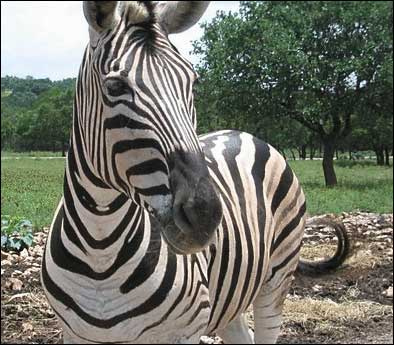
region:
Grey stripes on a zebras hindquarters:
[242, 141, 309, 240]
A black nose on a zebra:
[151, 145, 229, 249]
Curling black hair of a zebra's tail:
[292, 211, 356, 278]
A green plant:
[4, 210, 30, 252]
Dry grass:
[289, 290, 382, 324]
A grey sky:
[10, 7, 72, 58]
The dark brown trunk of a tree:
[287, 104, 346, 181]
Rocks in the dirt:
[6, 222, 49, 287]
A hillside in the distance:
[8, 70, 65, 124]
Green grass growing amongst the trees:
[297, 158, 382, 209]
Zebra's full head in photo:
[69, 2, 234, 255]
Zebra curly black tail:
[296, 203, 354, 287]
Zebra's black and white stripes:
[212, 236, 264, 297]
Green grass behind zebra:
[342, 186, 383, 204]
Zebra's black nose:
[165, 189, 221, 235]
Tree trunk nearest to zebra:
[320, 146, 332, 182]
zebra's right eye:
[96, 73, 130, 96]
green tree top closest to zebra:
[222, 13, 388, 118]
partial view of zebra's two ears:
[75, 0, 218, 44]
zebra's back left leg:
[246, 265, 296, 338]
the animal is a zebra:
[41, 0, 347, 343]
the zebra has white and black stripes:
[38, 1, 339, 341]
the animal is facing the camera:
[34, 0, 329, 341]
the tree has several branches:
[185, 0, 389, 181]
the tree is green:
[195, 0, 392, 176]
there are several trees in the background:
[7, 0, 391, 167]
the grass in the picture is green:
[6, 143, 390, 229]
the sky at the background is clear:
[6, 0, 390, 82]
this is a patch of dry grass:
[204, 298, 391, 321]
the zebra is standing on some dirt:
[21, 2, 366, 339]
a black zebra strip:
[116, 133, 164, 152]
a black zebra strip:
[121, 231, 164, 297]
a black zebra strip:
[150, 253, 177, 311]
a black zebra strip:
[52, 245, 107, 288]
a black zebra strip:
[63, 197, 101, 250]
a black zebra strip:
[134, 180, 175, 201]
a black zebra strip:
[210, 227, 228, 328]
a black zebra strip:
[214, 231, 243, 322]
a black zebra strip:
[234, 242, 255, 309]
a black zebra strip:
[247, 240, 263, 307]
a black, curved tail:
[295, 213, 364, 304]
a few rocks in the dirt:
[340, 200, 392, 254]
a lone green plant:
[0, 212, 37, 258]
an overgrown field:
[10, 163, 55, 242]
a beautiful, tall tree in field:
[204, 1, 380, 196]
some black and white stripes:
[210, 244, 273, 318]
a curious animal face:
[68, 10, 255, 264]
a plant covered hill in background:
[4, 45, 73, 159]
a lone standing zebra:
[39, 5, 345, 343]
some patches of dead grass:
[299, 288, 375, 332]